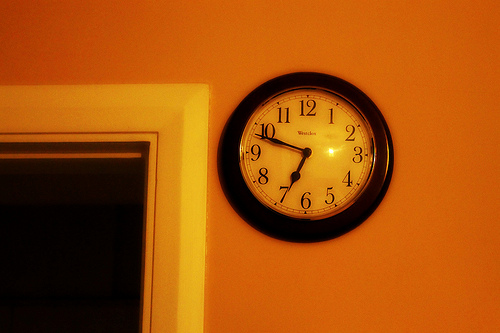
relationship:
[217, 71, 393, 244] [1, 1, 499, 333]
clock mounted on wall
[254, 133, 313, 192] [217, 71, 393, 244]
hands in middle of clock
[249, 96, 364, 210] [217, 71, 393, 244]
numbers printed on clock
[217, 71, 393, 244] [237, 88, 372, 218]
clock has face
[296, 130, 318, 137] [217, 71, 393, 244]
name on front of clock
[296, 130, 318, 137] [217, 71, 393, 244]
name on face of clock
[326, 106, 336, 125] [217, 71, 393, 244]
number 1 on front of clock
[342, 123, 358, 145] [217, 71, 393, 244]
number 2 on front of clock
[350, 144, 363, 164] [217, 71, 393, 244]
number 3 on front of clock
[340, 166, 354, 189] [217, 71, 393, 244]
number 4 on front of clock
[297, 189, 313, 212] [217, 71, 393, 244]
number 6 on front of clock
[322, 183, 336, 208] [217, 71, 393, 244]
number 5 on front of clock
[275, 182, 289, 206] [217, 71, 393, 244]
number 7 on front of clock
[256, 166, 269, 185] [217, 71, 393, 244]
number 8 on front of clock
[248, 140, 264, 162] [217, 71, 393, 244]
number 9 on front of clock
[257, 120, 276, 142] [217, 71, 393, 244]
number 10 on front of clock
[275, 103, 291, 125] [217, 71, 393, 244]
number 11 on front of clock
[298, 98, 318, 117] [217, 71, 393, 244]
number 12 on front of clock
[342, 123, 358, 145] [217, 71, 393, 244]
number 2 printed on clock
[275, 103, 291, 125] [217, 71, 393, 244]
number 11 printed on clock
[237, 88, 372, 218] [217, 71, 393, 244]
frame around clock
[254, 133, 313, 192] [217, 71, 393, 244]
hands on front of clock